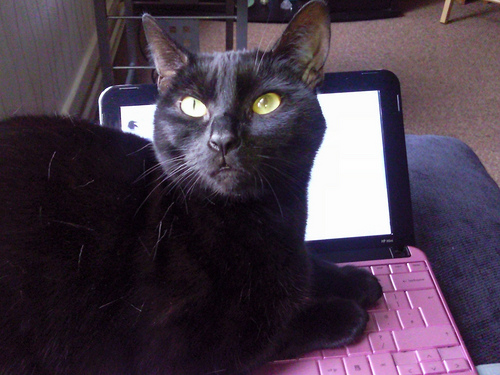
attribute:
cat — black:
[9, 1, 415, 369]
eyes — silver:
[172, 90, 292, 126]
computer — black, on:
[90, 75, 472, 372]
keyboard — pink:
[215, 260, 477, 375]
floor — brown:
[125, 7, 497, 186]